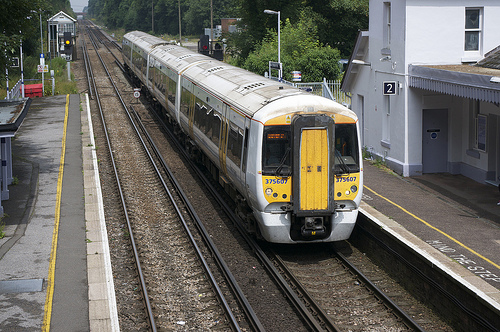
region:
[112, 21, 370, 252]
An incoming train at a train station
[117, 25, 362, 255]
An incoming train at a train station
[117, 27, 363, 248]
An incoming train at a train station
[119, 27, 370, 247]
the train is at the station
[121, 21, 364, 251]
the train is painted white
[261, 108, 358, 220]
the front of the train is painted yellow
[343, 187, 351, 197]
a headlight is on the train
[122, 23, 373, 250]
the train is made of metal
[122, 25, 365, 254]
the train is made of steel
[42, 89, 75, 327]
a line is on the platform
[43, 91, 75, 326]
the line is yellow in color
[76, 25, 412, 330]
the tracks are made of metal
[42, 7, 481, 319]
a train coming into the station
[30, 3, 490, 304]
a railway entering the station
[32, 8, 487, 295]
a train at the station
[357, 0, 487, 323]
the number two platform at a train station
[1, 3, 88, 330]
the platform at the train station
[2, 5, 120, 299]
a platform at a railway station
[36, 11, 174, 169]
a yellow semaphore at a train station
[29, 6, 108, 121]
a yellow semaphore at a rail station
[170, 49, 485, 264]
railway car at the station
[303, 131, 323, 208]
The door of a train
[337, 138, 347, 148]
Driver on the train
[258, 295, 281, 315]
Dark gravel between the tracks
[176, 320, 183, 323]
A white piece of trash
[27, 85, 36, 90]
A red object on the ground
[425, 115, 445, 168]
A door on the building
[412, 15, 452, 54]
A bright wall surface